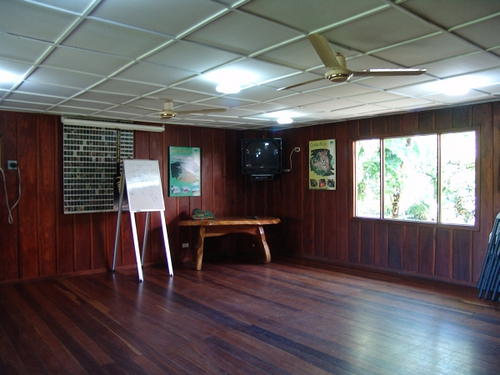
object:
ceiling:
[1, 2, 497, 132]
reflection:
[345, 309, 475, 374]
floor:
[0, 253, 499, 375]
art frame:
[168, 146, 202, 197]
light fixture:
[216, 83, 239, 95]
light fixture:
[278, 117, 293, 124]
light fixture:
[441, 85, 468, 95]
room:
[0, 0, 500, 375]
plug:
[182, 244, 190, 249]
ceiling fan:
[277, 33, 425, 92]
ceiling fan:
[116, 99, 229, 124]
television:
[239, 137, 283, 183]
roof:
[0, 0, 500, 132]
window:
[354, 131, 482, 232]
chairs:
[478, 209, 498, 305]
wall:
[0, 101, 500, 292]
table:
[178, 216, 281, 270]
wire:
[281, 147, 302, 172]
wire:
[0, 161, 22, 225]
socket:
[9, 160, 18, 170]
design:
[108, 20, 367, 120]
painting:
[308, 139, 337, 191]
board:
[123, 160, 165, 213]